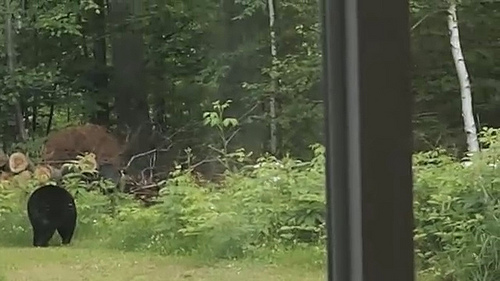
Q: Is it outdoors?
A: Yes, it is outdoors.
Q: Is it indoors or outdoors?
A: It is outdoors.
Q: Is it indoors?
A: No, it is outdoors.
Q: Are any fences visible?
A: No, there are no fences.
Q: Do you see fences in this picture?
A: No, there are no fences.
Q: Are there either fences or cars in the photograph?
A: No, there are no fences or cars.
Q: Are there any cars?
A: No, there are no cars.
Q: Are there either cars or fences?
A: No, there are no cars or fences.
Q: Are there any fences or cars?
A: No, there are no cars or fences.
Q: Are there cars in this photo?
A: No, there are no cars.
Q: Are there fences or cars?
A: No, there are no cars or fences.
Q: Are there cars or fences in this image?
A: No, there are no cars or fences.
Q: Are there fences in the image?
A: No, there are no fences.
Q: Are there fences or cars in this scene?
A: No, there are no fences or cars.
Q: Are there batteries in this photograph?
A: No, there are no batteries.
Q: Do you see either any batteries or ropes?
A: No, there are no batteries or ropes.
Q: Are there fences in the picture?
A: No, there are no fences.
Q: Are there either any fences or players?
A: No, there are no fences or players.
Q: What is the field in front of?
A: The field is in front of the trees.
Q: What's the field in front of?
A: The field is in front of the trees.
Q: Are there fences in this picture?
A: No, there are no fences.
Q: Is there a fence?
A: No, there are no fences.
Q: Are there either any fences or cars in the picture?
A: No, there are no fences or cars.